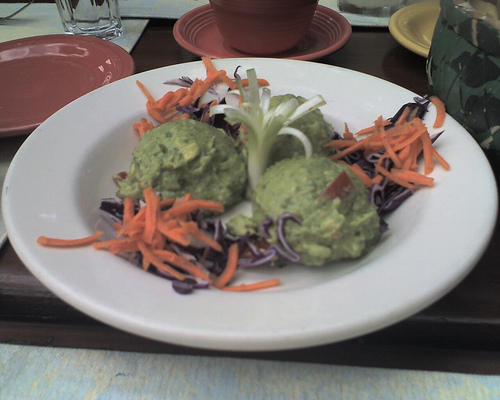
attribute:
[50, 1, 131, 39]
glass — clear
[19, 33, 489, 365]
plate — white , Reddish, ruddy , ceramic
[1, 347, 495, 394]
table — wooden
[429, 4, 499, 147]
pot — Large, round, greenish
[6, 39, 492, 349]
dish — Large, white, ceramic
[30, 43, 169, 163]
plate — empty, orange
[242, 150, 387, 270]
ball — lumpy, green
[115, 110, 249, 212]
ball — lumpy, green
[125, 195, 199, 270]
carrots — shredded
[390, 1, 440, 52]
yellow dish — Small, round, yellowish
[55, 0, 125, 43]
glass — clear, empty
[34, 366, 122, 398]
table — white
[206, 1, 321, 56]
bowl — orange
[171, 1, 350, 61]
saucer — orange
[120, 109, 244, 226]
balls — sticky, green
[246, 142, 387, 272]
balls — sticky, green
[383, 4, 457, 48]
plate — yellow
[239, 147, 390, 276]
lump — green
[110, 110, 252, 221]
ball — green, lumpy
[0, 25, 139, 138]
plate — empty, red